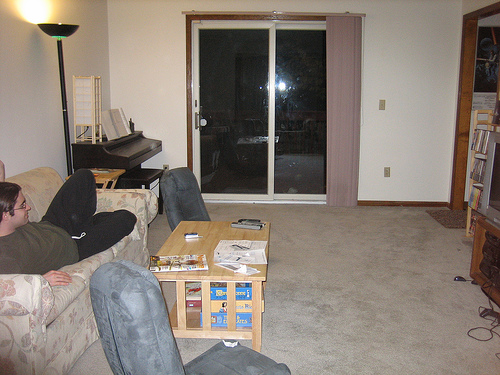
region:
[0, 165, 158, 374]
man is laying on floral couch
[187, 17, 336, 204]
sliding glass door is closed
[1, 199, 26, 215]
glasses are on man's face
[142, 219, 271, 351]
wooden coffee table is cluttered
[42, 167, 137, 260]
black pants are on man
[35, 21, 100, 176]
black lamp is turned on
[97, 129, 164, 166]
piano lid is closed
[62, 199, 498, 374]
beige carpet is dirty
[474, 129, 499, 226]
silver tv is turned off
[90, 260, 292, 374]
small blue chair is on floor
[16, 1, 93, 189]
the lamp is emitting light on wall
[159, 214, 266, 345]
the coffee table is made of wood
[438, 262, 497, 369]
cords are on the floor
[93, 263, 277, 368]
the chair is blue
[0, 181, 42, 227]
the man is wearing glasses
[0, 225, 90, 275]
the man's shirt is green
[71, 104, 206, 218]
the piano is black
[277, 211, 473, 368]
the carpet is brown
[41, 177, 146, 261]
the man's pants are black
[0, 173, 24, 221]
the man;s hair is brown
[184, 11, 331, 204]
sliding glass patio doors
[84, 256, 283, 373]
a grey floor gaming chair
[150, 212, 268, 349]
a light colored wood coffee table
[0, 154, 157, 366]
a man laying on a couch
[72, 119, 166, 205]
a black piano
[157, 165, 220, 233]
a grey floor gaming chair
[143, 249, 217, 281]
a magazine on a table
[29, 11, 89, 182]
a black floor lamp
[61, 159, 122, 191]
a wooden folding table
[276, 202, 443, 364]
a light grey carpet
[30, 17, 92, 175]
tall lamp next to piano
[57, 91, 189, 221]
piano in corner of room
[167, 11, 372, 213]
large glass sliding door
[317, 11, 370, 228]
curtain pulled to the side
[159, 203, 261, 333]
wooden table in middle of room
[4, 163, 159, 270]
young man lying on the couch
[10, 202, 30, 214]
glasses on man's face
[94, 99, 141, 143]
sheet music on piano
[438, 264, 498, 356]
cables lying on floor in front of TV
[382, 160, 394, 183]
power outlets against wall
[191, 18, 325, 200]
Glasses doors on the balcony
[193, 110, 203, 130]
Door handle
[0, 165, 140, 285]
Man lying on the couch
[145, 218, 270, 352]
Coffee table in the living room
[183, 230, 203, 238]
Cellphone on the table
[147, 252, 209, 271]
Magazine on the table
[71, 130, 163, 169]
Piano in the corner of the living room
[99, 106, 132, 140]
Music book on the piano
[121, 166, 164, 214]
Stool under the piano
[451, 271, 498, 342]
Black cables on the ground